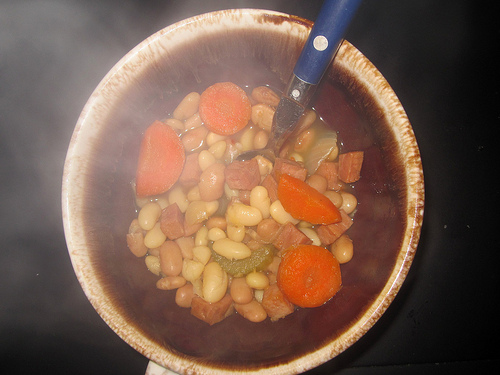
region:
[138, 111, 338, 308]
Beans and carrot stew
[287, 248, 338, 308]
A piece of cooked caroot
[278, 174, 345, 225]
A piece of cooked caroot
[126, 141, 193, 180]
A piece of cooked caroot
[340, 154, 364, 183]
A piece of cooked caroot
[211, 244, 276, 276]
A piece of cooked paprica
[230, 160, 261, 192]
A piece of cooked caroot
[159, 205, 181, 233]
A piece of cooked caroot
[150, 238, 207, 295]
White fully cooked beans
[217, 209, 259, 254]
White fully cooked beans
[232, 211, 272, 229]
vegetable in the soup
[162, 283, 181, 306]
vegetable in the soup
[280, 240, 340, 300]
vegetable in the soup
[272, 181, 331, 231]
vegetable in the soup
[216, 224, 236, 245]
vegetable in the soup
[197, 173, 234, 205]
vegetable in the soup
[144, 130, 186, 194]
vegetable in the soup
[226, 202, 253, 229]
vegetable in the soup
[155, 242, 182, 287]
vegetable in the soup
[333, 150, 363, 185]
vegetable in the soup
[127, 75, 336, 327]
orange carrots in soup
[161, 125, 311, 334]
yellow beans in soup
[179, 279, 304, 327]
brown meat in soup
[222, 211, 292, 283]
green vegetables in soup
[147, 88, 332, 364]
brown broth in soup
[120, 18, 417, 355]
soup in white bowl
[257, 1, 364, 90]
blue handle on spoon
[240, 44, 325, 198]
steel spoon in soup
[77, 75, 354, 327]
vegetables in dark soup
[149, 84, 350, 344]
meat and vegetables in stock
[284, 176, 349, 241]
the carrot is orange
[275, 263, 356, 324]
the carrot is orange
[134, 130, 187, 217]
the carrot is orange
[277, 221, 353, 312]
the carrot is orange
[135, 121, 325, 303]
the beans in a soup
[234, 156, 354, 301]
the beans in a soup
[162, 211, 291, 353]
the beans in a soup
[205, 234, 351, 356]
the beans in a soup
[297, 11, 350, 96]
spoon's handle is blue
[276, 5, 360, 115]
spoon's handle is blue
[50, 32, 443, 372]
the soup is red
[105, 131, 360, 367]
the soup is red